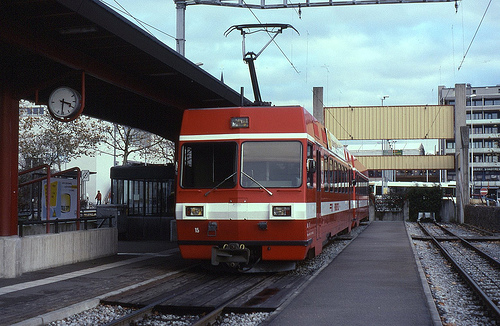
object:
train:
[174, 105, 378, 274]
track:
[107, 274, 268, 324]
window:
[333, 160, 339, 193]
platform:
[0, 227, 174, 325]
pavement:
[264, 218, 435, 325]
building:
[312, 87, 455, 217]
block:
[1, 235, 18, 279]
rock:
[116, 305, 124, 310]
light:
[185, 206, 204, 217]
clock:
[47, 86, 82, 119]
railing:
[17, 215, 119, 236]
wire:
[243, 0, 260, 25]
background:
[0, 0, 500, 244]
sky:
[100, 0, 498, 114]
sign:
[41, 177, 79, 221]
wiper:
[203, 171, 273, 198]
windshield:
[241, 140, 304, 190]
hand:
[61, 98, 65, 114]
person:
[95, 190, 102, 205]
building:
[438, 83, 500, 207]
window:
[485, 98, 495, 104]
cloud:
[255, 4, 500, 76]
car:
[375, 193, 402, 212]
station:
[0, 20, 445, 326]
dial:
[73, 100, 77, 102]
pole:
[174, 0, 186, 53]